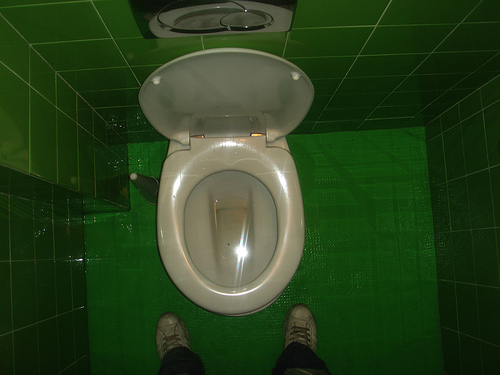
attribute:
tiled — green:
[2, 0, 494, 369]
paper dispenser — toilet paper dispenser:
[117, 2, 302, 44]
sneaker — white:
[284, 304, 330, 355]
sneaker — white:
[145, 300, 196, 367]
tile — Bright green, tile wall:
[421, 73, 498, 371]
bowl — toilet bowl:
[171, 139, 362, 306]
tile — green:
[367, 0, 429, 62]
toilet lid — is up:
[128, 47, 318, 140]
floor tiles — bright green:
[81, 125, 445, 374]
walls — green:
[1, 0, 499, 374]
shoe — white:
[155, 310, 190, 364]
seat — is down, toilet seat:
[153, 137, 305, 316]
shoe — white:
[280, 302, 318, 355]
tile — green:
[80, 128, 434, 370]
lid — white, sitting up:
[129, 54, 393, 195]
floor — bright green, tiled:
[125, 126, 440, 373]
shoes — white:
[152, 308, 320, 345]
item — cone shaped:
[340, 187, 415, 297]